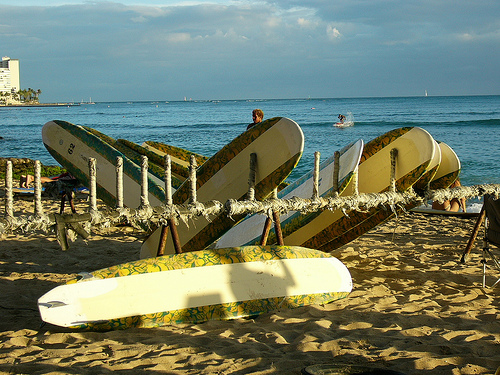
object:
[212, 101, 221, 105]
sailboats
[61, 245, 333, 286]
design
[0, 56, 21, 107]
building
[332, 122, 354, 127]
surfboard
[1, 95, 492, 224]
blue water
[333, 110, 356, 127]
swimming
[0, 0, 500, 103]
blue sky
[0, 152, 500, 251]
rack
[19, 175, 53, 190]
person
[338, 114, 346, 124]
man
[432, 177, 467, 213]
woman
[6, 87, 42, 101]
palm trees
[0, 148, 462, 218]
sticks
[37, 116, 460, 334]
surfboards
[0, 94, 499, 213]
blue ocean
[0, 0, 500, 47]
clouds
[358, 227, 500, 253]
shadows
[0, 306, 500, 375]
shadows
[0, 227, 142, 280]
shadows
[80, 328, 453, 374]
shadows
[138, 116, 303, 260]
surfboard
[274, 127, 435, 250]
surfboard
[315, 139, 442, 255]
surfboard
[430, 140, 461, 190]
surfboard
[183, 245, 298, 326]
shadow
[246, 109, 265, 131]
man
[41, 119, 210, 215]
surfboards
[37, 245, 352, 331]
surfboard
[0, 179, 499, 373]
beach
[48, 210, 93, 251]
feet